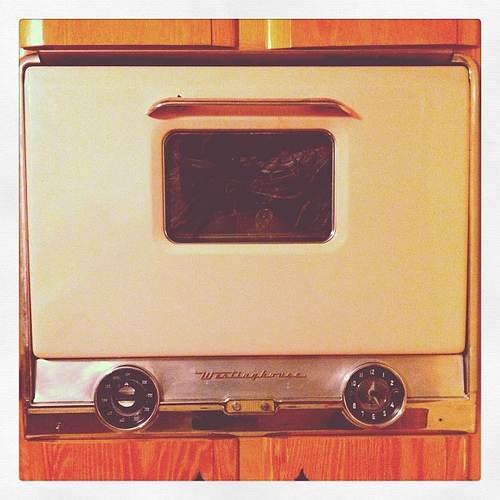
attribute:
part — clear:
[167, 131, 334, 244]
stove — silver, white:
[21, 50, 476, 433]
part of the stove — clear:
[161, 125, 337, 248]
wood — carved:
[21, 17, 484, 49]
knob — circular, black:
[92, 363, 163, 434]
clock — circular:
[342, 362, 411, 433]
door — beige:
[26, 67, 465, 354]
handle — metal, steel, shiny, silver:
[149, 96, 362, 122]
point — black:
[295, 467, 309, 481]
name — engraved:
[195, 369, 307, 382]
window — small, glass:
[161, 126, 337, 245]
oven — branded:
[22, 47, 478, 435]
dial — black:
[92, 362, 163, 433]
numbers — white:
[99, 372, 154, 425]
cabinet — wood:
[23, 437, 482, 481]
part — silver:
[29, 358, 473, 407]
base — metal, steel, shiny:
[32, 358, 471, 415]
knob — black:
[340, 361, 408, 430]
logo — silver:
[195, 369, 307, 381]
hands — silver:
[368, 379, 380, 406]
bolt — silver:
[232, 400, 243, 411]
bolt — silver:
[259, 401, 269, 413]